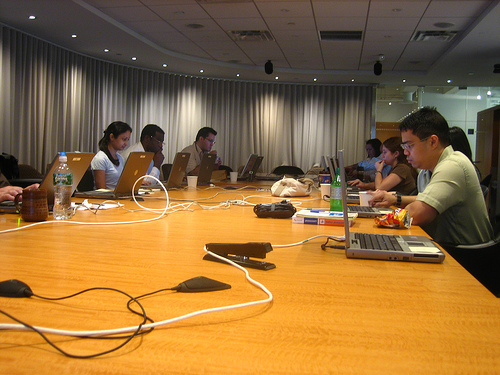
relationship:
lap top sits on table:
[335, 145, 447, 263] [1, 175, 498, 371]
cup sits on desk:
[14, 187, 48, 222] [1, 180, 498, 372]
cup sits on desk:
[185, 175, 197, 192] [1, 180, 498, 372]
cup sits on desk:
[228, 170, 238, 184] [1, 180, 498, 372]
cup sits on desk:
[320, 182, 331, 200] [1, 180, 498, 372]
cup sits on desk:
[358, 190, 372, 205] [1, 180, 498, 372]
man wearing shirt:
[366, 107, 498, 247] [415, 146, 492, 246]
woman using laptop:
[87, 121, 137, 186] [154, 145, 193, 182]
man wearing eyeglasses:
[129, 121, 169, 188] [151, 136, 166, 146]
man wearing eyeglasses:
[171, 124, 214, 167] [204, 139, 216, 147]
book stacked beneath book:
[290, 211, 352, 226] [292, 208, 359, 227]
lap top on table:
[73, 150, 155, 199] [1, 175, 498, 371]